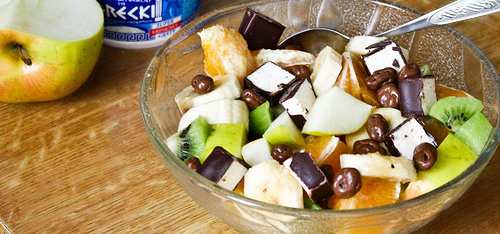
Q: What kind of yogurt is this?
A: Greek.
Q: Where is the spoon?
A: In the bowl.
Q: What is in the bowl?
A: Fruit salad.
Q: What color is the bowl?
A: Clear.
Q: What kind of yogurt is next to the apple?
A: Greek.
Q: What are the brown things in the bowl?
A: Chocolate covered raisins.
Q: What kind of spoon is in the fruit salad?
A: Silver spoon.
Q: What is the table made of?
A: Wood.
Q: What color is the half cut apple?
A: Yellow.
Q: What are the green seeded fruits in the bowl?
A: Kiwi.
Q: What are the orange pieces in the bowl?
A: Oranges.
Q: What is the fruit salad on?
A: A table.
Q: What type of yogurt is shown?
A: Greek.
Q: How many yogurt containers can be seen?
A: 1.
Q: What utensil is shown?
A: Spoon.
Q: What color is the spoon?
A: Silver.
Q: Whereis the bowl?
A: On the table.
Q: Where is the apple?
A: Top left corner.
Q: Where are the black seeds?
A: In kiwi slices.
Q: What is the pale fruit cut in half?
A: An apple.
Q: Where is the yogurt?
A: Behind the apple.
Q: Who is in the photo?
A: No one.